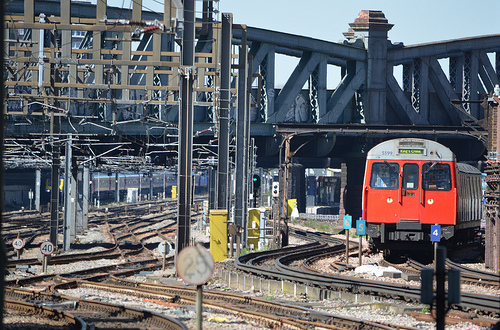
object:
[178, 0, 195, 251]
support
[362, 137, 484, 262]
train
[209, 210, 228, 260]
box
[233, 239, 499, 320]
tracks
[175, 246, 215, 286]
sign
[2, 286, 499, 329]
ground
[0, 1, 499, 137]
bridge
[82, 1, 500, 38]
sky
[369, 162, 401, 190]
window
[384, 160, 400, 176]
wiper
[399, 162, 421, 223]
door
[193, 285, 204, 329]
pole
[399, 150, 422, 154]
sign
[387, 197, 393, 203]
lights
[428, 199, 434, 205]
lights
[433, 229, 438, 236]
number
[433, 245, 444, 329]
pole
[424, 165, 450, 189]
driven